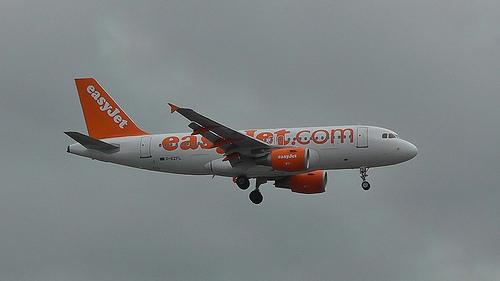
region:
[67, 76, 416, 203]
the plane is orange and white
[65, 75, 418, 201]
a plane in the air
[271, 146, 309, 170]
the wing engine is orange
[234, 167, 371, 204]
the landing gear is out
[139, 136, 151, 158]
the rear door is closed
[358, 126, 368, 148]
the front door is closed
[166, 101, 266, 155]
a wing on the plane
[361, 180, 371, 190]
the tire is black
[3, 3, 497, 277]
the skies are gray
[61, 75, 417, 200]
an airplane in the sky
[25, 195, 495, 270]
the sky below the airplane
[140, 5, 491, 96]
the clouds above the airplane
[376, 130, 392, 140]
the window on the airplane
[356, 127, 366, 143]
the door on the airplane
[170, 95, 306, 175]
the wing on the airplane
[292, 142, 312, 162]
the propeller on the airplane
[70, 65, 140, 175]
the tail wing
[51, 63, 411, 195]
an orange and white airplane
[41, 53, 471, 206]
Easy jet in flight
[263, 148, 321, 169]
Orange engines on either side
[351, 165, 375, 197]
landing gear out for landing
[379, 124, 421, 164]
White nose of jet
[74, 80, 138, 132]
Orange tail of jet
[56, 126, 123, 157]
Wing on back of jet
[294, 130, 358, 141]
Windows along the side of the plane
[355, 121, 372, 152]
Door of plane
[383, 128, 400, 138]
Windshield of plan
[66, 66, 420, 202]
a white and orange airplane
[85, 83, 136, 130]
writing on the tail of the plane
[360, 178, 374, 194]
the wheel on the plane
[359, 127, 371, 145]
the door on the plane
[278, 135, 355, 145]
windows on the plane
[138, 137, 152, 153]
a back door on the plane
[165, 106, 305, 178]
the wing on the plane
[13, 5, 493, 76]
clouds behind the plane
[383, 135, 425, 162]
the nose of the plane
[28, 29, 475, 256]
a plane flying in the sky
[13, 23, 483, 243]
a jet flying in a gray sky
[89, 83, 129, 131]
it says : easyjet in white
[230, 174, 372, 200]
the landing gear of the plane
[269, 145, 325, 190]
the two orange turbines of the plane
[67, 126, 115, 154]
the horizontal stabilizer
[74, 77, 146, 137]
the vertical stabilizer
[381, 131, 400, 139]
the plane cockpit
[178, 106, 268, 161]
one wing of the plane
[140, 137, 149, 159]
one exit door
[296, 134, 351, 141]
the passenger windows